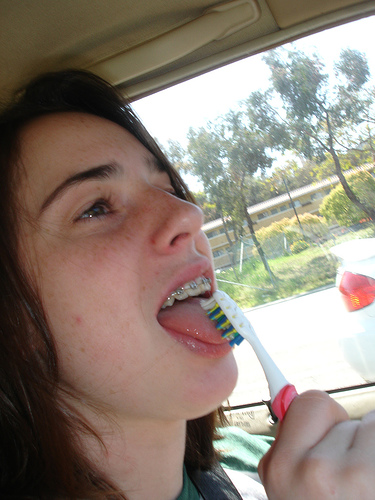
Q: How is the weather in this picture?
A: It is clear.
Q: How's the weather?
A: It is clear.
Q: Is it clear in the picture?
A: Yes, it is clear.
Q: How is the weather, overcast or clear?
A: It is clear.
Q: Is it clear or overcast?
A: It is clear.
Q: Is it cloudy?
A: No, it is clear.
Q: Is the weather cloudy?
A: No, it is clear.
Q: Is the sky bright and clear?
A: Yes, the sky is bright and clear.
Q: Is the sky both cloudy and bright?
A: No, the sky is bright but clear.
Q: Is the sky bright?
A: Yes, the sky is bright.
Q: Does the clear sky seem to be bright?
A: Yes, the sky is bright.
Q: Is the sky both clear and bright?
A: Yes, the sky is clear and bright.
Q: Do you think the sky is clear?
A: Yes, the sky is clear.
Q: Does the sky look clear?
A: Yes, the sky is clear.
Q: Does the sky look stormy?
A: No, the sky is clear.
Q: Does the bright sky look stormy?
A: No, the sky is clear.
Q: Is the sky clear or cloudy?
A: The sky is clear.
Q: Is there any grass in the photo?
A: Yes, there is grass.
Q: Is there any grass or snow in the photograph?
A: Yes, there is grass.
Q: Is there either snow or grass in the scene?
A: Yes, there is grass.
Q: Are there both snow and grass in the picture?
A: No, there is grass but no snow.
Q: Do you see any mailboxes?
A: No, there are no mailboxes.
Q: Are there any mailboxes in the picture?
A: No, there are no mailboxes.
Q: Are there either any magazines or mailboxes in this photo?
A: No, there are no mailboxes or magazines.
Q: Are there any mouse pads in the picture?
A: No, there are no mouse pads.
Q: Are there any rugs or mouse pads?
A: No, there are no mouse pads or rugs.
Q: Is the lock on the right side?
A: Yes, the lock is on the right of the image.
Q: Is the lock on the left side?
A: No, the lock is on the right of the image.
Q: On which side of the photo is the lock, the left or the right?
A: The lock is on the right of the image.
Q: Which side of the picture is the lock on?
A: The lock is on the right of the image.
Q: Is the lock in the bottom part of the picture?
A: Yes, the lock is in the bottom of the image.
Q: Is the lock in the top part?
A: No, the lock is in the bottom of the image.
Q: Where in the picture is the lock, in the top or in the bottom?
A: The lock is in the bottom of the image.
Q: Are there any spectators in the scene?
A: No, there are no spectators.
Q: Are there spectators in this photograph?
A: No, there are no spectators.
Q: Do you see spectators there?
A: No, there are no spectators.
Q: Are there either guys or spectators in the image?
A: No, there are no spectators or guys.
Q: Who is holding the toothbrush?
A: The girl is holding the toothbrush.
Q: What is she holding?
A: The girl is holding the toothbrush.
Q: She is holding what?
A: The girl is holding the toothbrush.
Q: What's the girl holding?
A: The girl is holding the toothbrush.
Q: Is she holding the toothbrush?
A: Yes, the girl is holding the toothbrush.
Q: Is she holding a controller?
A: No, the girl is holding the toothbrush.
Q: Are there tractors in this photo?
A: No, there are no tractors.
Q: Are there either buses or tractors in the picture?
A: No, there are no tractors or buses.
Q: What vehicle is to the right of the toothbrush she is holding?
A: The vehicle is a car.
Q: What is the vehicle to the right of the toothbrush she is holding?
A: The vehicle is a car.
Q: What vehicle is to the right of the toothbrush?
A: The vehicle is a car.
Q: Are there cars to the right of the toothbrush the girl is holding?
A: Yes, there is a car to the right of the toothbrush.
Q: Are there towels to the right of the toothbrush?
A: No, there is a car to the right of the toothbrush.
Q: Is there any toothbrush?
A: Yes, there is a toothbrush.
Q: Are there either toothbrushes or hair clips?
A: Yes, there is a toothbrush.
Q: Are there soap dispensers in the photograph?
A: No, there are no soap dispensers.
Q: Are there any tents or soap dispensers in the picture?
A: No, there are no soap dispensers or tents.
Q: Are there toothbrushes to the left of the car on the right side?
A: Yes, there is a toothbrush to the left of the car.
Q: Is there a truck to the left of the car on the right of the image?
A: No, there is a toothbrush to the left of the car.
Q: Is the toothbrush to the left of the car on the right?
A: Yes, the toothbrush is to the left of the car.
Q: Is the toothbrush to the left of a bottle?
A: No, the toothbrush is to the left of the car.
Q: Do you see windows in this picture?
A: Yes, there is a window.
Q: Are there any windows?
A: Yes, there is a window.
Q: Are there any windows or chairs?
A: Yes, there is a window.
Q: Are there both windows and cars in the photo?
A: Yes, there are both a window and a car.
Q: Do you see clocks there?
A: No, there are no clocks.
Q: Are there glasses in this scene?
A: No, there are no glasses.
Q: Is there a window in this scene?
A: Yes, there are windows.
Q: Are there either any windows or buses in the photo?
A: Yes, there are windows.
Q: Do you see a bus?
A: No, there are no buses.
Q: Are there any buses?
A: No, there are no buses.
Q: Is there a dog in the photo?
A: No, there are no dogs.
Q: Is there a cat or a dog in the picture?
A: No, there are no dogs or cats.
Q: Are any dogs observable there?
A: No, there are no dogs.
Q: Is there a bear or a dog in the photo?
A: No, there are no dogs or bears.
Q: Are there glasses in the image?
A: No, there are no glasses.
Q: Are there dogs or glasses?
A: No, there are no glasses or dogs.